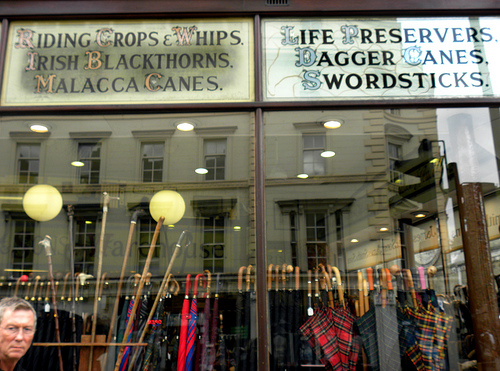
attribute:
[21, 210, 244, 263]
sign — yellow, black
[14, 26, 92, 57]
letters — black, gold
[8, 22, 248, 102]
font — black, brown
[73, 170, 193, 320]
canes — wooden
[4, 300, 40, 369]
man — serious looking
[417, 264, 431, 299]
handle — pink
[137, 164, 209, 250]
lights — yellow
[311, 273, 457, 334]
umbrella — red, black, plaid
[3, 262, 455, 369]
umbrellas — multicolored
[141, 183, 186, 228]
globe — yellow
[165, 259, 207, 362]
umbrella — red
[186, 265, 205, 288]
handle — red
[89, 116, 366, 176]
lighting — recessed